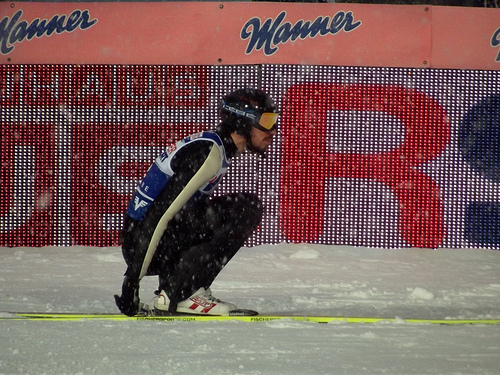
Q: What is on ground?
A: White snow and ice.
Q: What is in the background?
A: Digital read out.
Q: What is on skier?
A: Snow suit.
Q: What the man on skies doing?
A: Crouched.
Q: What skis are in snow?
A: Yellow.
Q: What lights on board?
A: Red.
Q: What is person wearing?
A: Vest.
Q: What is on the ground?
A: Snow.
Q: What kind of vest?
A: Competition.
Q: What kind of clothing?
A: Jumpsuit.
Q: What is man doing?
A: Squatting.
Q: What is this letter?
A: R.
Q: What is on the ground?
A: Ski.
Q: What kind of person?
A: Athlete.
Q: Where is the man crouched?
A: On skis.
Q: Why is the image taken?
A: Remembrance.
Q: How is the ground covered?
A: With snow.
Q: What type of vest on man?
A: Blue and white vest.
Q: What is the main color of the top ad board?
A: Pink.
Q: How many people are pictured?
A: One.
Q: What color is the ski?
A: Yellow.